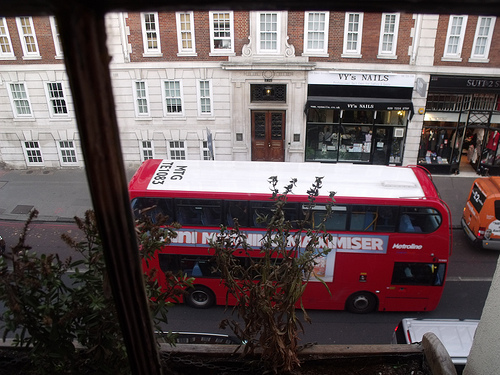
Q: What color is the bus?
A: Red.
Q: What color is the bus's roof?
A: White.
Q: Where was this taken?
A: City street.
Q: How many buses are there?
A: 1.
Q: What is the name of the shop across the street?
A: Vy's Nails.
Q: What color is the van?
A: Orange.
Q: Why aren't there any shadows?
A: Not sunny.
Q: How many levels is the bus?
A: 2.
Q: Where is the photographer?
A: Inside the building.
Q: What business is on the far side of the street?
A: Nail Salon.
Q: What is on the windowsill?
A: Plants.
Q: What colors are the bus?
A: Red and white.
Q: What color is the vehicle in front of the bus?
A: Orange.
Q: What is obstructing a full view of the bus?
A: A dried out plant.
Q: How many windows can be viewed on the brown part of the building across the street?
A: 12.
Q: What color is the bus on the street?
A: Red with a white top.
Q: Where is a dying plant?
A: Outside a window.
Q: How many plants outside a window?
A: Two.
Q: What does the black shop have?
A: VY'S NAILS above it over white.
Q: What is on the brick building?
A: Many white windows.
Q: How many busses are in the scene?
A: One.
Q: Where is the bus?
A: On the street.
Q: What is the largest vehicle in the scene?
A: A bus.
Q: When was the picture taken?
A: Daytime.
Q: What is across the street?
A: A building.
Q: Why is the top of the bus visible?
A: The picture was taken from a window up high.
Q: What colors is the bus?
A: Red and white.